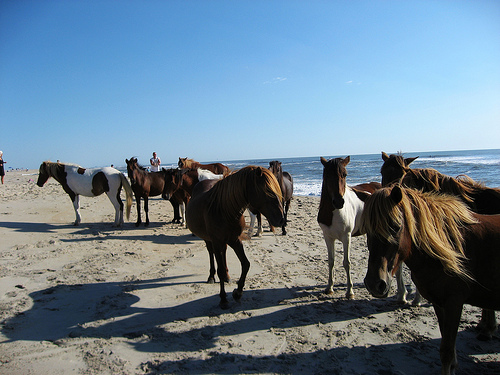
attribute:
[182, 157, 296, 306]
horse — brown, looking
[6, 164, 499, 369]
beach — sandy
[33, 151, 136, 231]
horse — white, brown, sideways, standing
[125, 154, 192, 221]
horse — brown, sideways, standing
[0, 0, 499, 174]
sky — clear, blue, cloudless, daytime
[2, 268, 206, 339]
shadow — horse's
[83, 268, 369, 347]
shadow — horse's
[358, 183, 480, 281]
mane — horse's, blond, flowing, long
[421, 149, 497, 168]
wave — ocean's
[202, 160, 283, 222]
mane — blond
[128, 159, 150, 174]
mane — dark, brown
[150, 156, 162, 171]
shirt — white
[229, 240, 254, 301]
leg — horse's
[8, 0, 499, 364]
picture — horses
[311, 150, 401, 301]
horse — white, brown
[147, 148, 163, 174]
person — standing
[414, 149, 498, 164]
cap — white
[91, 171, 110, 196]
spot — brown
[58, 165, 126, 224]
body — white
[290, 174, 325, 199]
foam — white, sea's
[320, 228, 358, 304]
legs — white